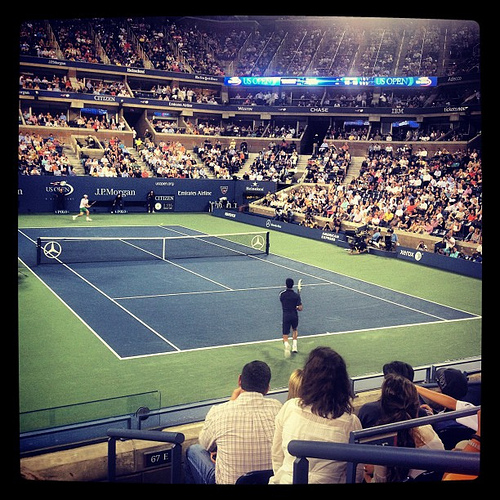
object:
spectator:
[11, 17, 482, 266]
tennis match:
[17, 205, 487, 420]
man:
[280, 278, 301, 361]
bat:
[297, 279, 303, 292]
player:
[71, 194, 91, 222]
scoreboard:
[222, 73, 437, 90]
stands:
[21, 15, 484, 263]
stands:
[8, 367, 483, 491]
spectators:
[369, 375, 449, 483]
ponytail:
[386, 410, 416, 481]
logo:
[249, 233, 269, 251]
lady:
[268, 343, 370, 486]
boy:
[147, 189, 156, 214]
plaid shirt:
[197, 391, 284, 484]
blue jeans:
[234, 466, 274, 486]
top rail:
[288, 438, 481, 475]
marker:
[44, 241, 64, 262]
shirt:
[279, 290, 302, 311]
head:
[238, 359, 270, 399]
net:
[32, 226, 272, 262]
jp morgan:
[94, 188, 137, 197]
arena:
[17, 14, 482, 484]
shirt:
[79, 196, 89, 208]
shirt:
[268, 396, 362, 484]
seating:
[18, 22, 481, 266]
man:
[187, 359, 285, 496]